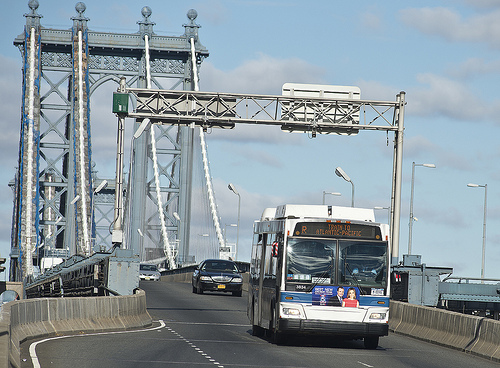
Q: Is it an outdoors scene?
A: Yes, it is outdoors.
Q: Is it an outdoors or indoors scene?
A: It is outdoors.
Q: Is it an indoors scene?
A: No, it is outdoors.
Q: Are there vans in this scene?
A: No, there are no vans.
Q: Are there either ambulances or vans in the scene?
A: No, there are no vans or ambulances.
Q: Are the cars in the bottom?
A: Yes, the cars are in the bottom of the image.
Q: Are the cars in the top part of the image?
A: No, the cars are in the bottom of the image.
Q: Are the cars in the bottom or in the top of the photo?
A: The cars are in the bottom of the image.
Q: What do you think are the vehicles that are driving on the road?
A: The vehicles are cars.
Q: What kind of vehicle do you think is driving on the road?
A: The vehicles are cars.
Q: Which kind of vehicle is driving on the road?
A: The vehicles are cars.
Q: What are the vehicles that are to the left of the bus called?
A: The vehicles are cars.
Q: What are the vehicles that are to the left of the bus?
A: The vehicles are cars.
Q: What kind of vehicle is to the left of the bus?
A: The vehicles are cars.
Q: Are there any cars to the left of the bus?
A: Yes, there are cars to the left of the bus.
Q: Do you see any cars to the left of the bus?
A: Yes, there are cars to the left of the bus.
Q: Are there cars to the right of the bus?
A: No, the cars are to the left of the bus.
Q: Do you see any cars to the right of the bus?
A: No, the cars are to the left of the bus.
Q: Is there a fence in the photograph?
A: No, there are no fences.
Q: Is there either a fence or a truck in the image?
A: No, there are no fences or trucks.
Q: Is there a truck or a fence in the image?
A: No, there are no fences or trucks.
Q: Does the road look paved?
A: Yes, the road is paved.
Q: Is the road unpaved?
A: No, the road is paved.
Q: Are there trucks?
A: No, there are no trucks.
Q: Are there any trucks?
A: No, there are no trucks.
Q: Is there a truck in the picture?
A: No, there are no trucks.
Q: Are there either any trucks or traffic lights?
A: No, there are no trucks or traffic lights.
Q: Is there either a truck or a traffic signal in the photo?
A: No, there are no trucks or traffic lights.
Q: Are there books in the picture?
A: No, there are no books.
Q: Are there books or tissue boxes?
A: No, there are no books or tissue boxes.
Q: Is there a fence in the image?
A: No, there are no fences.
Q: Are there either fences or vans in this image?
A: No, there are no fences or vans.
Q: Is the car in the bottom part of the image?
A: Yes, the car is in the bottom of the image.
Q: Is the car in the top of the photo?
A: No, the car is in the bottom of the image.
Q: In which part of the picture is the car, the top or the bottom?
A: The car is in the bottom of the image.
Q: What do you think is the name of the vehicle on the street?
A: The vehicle is a car.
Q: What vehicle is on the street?
A: The vehicle is a car.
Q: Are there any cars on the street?
A: Yes, there is a car on the street.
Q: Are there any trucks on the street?
A: No, there is a car on the street.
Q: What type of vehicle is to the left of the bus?
A: The vehicle is a car.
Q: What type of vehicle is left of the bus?
A: The vehicle is a car.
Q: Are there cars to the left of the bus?
A: Yes, there is a car to the left of the bus.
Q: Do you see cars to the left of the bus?
A: Yes, there is a car to the left of the bus.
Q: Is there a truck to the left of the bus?
A: No, there is a car to the left of the bus.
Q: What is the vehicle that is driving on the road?
A: The vehicle is a car.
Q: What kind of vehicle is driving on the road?
A: The vehicle is a car.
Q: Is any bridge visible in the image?
A: Yes, there is a bridge.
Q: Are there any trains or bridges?
A: Yes, there is a bridge.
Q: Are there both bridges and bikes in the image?
A: No, there is a bridge but no bikes.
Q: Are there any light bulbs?
A: No, there are no light bulbs.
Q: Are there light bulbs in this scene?
A: No, there are no light bulbs.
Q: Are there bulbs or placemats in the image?
A: No, there are no bulbs or placemats.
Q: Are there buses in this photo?
A: Yes, there is a bus.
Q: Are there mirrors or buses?
A: Yes, there is a bus.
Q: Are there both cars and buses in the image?
A: Yes, there are both a bus and a car.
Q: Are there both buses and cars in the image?
A: Yes, there are both a bus and a car.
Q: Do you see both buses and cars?
A: Yes, there are both a bus and a car.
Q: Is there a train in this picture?
A: No, there are no trains.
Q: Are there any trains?
A: No, there are no trains.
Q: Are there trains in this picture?
A: No, there are no trains.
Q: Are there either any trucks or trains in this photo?
A: No, there are no trains or trucks.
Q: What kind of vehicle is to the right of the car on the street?
A: The vehicle is a bus.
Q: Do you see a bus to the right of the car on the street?
A: Yes, there is a bus to the right of the car.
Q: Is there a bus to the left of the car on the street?
A: No, the bus is to the right of the car.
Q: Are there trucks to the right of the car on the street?
A: No, there is a bus to the right of the car.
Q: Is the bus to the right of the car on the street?
A: Yes, the bus is to the right of the car.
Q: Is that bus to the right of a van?
A: No, the bus is to the right of the car.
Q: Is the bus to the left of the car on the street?
A: No, the bus is to the right of the car.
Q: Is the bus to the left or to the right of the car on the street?
A: The bus is to the right of the car.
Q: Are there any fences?
A: No, there are no fences.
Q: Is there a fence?
A: No, there are no fences.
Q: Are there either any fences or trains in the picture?
A: No, there are no fences or trains.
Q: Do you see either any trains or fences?
A: No, there are no fences or trains.